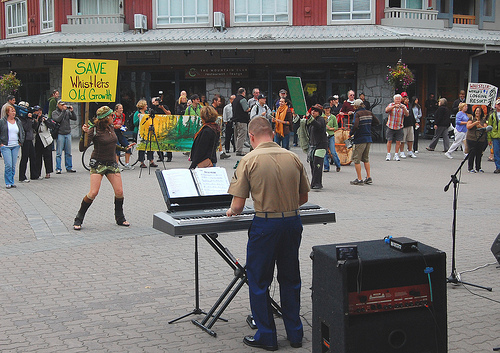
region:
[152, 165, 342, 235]
it is musical keyboard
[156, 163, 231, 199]
it is musical book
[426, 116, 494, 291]
it is mic with stand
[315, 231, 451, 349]
it is speaker box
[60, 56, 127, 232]
lady having yellow board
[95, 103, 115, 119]
lady wearing cap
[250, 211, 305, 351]
man wearing blue pant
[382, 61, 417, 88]
it is flower cent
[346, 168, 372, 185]
man wearing shoe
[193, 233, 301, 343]
it is keyboard stand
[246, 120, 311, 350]
Man playing the keyboard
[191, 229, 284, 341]
black keyboard stand under the keyboard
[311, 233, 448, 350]
Black speaker in back of the man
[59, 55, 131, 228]
woman walking with a protest sign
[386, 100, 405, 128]
man wearing red and white plaid shirt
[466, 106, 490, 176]
woman wearing a black outfit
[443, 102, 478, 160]
woman walking among the crowd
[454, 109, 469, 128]
purple shirt woman is wearing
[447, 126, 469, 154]
woman is wearing white pants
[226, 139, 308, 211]
tan shirt the man is wearing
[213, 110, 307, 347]
Marine playing a keyboard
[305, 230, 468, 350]
Amp on the sidwalk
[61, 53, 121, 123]
woman holding a sign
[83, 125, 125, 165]
woman wearing a brown shirt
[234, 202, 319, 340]
man wearing blue pants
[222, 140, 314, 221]
man wearing a brown shirt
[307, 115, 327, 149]
woman wearing a black shirt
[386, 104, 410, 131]
man wearing a plaid shirt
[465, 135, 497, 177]
woman with black pants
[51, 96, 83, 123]
man holding a camera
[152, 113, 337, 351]
A man playing a keyboard.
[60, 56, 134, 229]
A woman holding a sign.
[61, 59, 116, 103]
A yellow sign with writing.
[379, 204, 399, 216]
Part of the road.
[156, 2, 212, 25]
The windows on the building.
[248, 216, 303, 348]
The man's blue pants.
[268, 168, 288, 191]
Part of a brown shirt.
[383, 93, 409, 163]
A man standing on the street.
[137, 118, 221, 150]
A colorful sign.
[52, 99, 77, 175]
A man holding a camera.